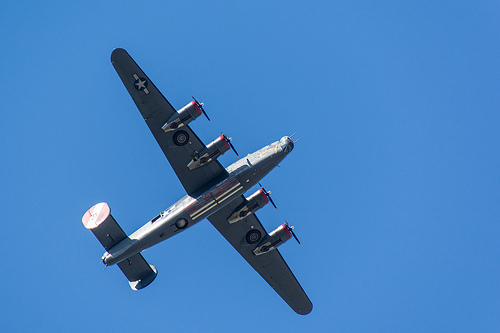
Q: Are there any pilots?
A: No, there are no pilots.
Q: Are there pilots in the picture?
A: No, there are no pilots.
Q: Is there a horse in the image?
A: No, there are no horses.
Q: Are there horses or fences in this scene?
A: No, there are no horses or fences.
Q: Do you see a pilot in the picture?
A: No, there are no pilots.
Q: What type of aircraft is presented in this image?
A: The aircraft is a jet.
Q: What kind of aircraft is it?
A: The aircraft is a jet.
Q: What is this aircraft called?
A: This is a jet.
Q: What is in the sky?
A: The jet is in the sky.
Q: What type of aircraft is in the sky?
A: The aircraft is a jet.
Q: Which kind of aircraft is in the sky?
A: The aircraft is a jet.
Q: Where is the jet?
A: The jet is in the sky.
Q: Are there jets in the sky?
A: Yes, there is a jet in the sky.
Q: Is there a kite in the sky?
A: No, there is a jet in the sky.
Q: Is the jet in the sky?
A: Yes, the jet is in the sky.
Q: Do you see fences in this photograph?
A: No, there are no fences.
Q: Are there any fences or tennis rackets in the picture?
A: No, there are no fences or tennis rackets.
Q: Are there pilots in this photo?
A: No, there are no pilots.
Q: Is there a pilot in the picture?
A: No, there are no pilots.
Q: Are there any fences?
A: No, there are no fences.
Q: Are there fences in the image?
A: No, there are no fences.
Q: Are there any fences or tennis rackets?
A: No, there are no fences or tennis rackets.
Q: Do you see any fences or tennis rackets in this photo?
A: No, there are no fences or tennis rackets.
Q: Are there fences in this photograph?
A: No, there are no fences.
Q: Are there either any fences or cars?
A: No, there are no fences or cars.